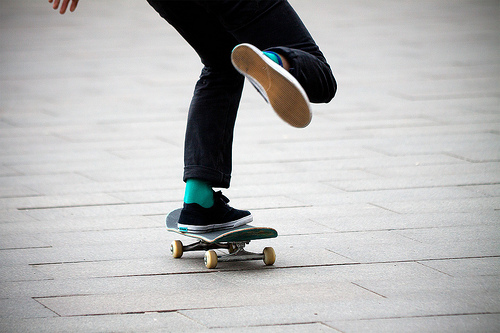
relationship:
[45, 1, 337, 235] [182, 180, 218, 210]
skater wearing sock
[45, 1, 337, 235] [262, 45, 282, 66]
skater wearing sock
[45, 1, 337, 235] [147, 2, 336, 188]
skater wearing pants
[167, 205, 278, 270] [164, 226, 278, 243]
skateboard has edge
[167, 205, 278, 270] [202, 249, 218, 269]
skateboard has wheel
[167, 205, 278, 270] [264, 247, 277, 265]
skateboard has wheel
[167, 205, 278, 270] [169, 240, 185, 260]
skateboard has wheel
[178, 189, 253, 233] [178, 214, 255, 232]
sneaker has edge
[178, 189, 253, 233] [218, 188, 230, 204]
sneaker has shoelace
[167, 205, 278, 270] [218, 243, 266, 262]
skateboard has axle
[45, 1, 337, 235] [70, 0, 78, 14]
skater has finger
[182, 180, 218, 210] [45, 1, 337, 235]
sock on skater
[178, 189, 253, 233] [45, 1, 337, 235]
sneaker on skater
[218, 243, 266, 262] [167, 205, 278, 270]
axle on skateboard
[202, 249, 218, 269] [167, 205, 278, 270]
wheel on skateboard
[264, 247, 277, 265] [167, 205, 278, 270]
wheel on skateboard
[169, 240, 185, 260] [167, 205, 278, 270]
wheel on skateboard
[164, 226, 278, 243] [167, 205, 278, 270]
edge of skateboard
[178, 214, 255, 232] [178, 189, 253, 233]
edge of sneaker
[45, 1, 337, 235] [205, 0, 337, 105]
skater has leg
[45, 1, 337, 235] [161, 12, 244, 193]
skater has leg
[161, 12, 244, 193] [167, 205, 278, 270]
leg on skateboard